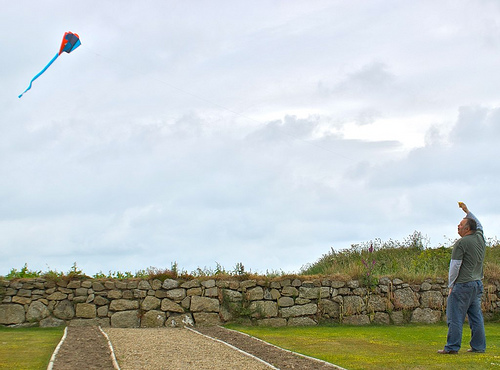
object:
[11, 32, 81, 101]
kite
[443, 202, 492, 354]
man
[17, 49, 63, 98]
tail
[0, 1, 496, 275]
air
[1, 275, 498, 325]
wall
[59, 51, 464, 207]
string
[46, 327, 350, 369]
path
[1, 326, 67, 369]
grass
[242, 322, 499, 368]
grass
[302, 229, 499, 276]
mound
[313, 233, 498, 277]
grass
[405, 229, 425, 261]
weeds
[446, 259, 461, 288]
shirt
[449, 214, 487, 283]
shirt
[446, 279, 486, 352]
jeans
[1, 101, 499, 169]
cloud cover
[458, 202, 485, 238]
arm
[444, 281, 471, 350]
legs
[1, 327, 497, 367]
ground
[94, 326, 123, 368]
line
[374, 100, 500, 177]
cloud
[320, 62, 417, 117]
cloud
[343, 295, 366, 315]
stone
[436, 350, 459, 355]
shoe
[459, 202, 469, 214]
hand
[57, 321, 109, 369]
dirt